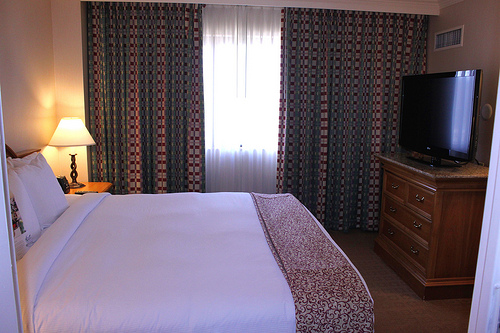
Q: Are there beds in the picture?
A: Yes, there is a bed.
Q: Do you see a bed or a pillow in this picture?
A: Yes, there is a bed.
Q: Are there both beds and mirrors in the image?
A: No, there is a bed but no mirrors.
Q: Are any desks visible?
A: No, there are no desks.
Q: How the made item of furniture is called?
A: The piece of furniture is a bed.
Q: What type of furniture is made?
A: The furniture is a bed.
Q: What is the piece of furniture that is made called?
A: The piece of furniture is a bed.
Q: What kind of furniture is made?
A: The furniture is a bed.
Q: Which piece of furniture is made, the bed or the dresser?
A: The bed is made.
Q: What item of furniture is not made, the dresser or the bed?
A: The dresser is not made.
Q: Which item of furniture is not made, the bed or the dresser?
A: The dresser is not made.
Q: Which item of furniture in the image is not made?
A: The piece of furniture is a dresser.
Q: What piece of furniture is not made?
A: The piece of furniture is a dresser.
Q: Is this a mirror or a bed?
A: This is a bed.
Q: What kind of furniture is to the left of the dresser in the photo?
A: The piece of furniture is a bed.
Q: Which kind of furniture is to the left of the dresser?
A: The piece of furniture is a bed.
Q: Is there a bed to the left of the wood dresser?
A: Yes, there is a bed to the left of the dresser.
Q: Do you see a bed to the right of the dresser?
A: No, the bed is to the left of the dresser.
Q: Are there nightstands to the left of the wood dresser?
A: No, there is a bed to the left of the dresser.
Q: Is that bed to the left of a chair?
A: No, the bed is to the left of a dresser.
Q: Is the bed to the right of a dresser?
A: No, the bed is to the left of a dresser.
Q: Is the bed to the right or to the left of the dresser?
A: The bed is to the left of the dresser.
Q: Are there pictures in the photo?
A: No, there are no pictures.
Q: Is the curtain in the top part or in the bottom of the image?
A: The curtain is in the top of the image.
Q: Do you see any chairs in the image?
A: No, there are no chairs.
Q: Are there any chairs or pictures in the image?
A: No, there are no chairs or pictures.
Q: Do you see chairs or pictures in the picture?
A: No, there are no chairs or pictures.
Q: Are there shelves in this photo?
A: No, there are no shelves.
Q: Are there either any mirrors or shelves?
A: No, there are no shelves or mirrors.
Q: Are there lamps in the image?
A: Yes, there is a lamp.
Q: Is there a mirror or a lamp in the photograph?
A: Yes, there is a lamp.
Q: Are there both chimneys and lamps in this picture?
A: No, there is a lamp but no chimneys.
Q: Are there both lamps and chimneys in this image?
A: No, there is a lamp but no chimneys.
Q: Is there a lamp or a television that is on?
A: Yes, the lamp is on.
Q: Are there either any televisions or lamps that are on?
A: Yes, the lamp is on.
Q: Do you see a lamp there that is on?
A: Yes, there is a lamp that is on.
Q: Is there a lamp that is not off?
A: Yes, there is a lamp that is on.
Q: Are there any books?
A: No, there are no books.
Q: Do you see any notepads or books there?
A: No, there are no books or notepads.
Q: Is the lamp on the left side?
A: Yes, the lamp is on the left of the image.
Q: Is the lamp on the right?
A: No, the lamp is on the left of the image.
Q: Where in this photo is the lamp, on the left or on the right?
A: The lamp is on the left of the image.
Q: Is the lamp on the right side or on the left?
A: The lamp is on the left of the image.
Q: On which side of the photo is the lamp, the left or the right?
A: The lamp is on the left of the image.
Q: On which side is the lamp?
A: The lamp is on the left of the image.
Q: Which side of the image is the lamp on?
A: The lamp is on the left of the image.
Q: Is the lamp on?
A: Yes, the lamp is on.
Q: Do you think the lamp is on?
A: Yes, the lamp is on.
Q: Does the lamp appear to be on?
A: Yes, the lamp is on.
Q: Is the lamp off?
A: No, the lamp is on.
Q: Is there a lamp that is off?
A: No, there is a lamp but it is on.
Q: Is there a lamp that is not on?
A: No, there is a lamp but it is on.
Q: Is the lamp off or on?
A: The lamp is on.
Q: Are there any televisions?
A: Yes, there is a television.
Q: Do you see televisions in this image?
A: Yes, there is a television.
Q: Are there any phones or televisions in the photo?
A: Yes, there is a television.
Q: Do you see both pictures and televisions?
A: No, there is a television but no pictures.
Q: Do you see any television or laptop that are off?
A: Yes, the television is off.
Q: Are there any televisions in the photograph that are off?
A: Yes, there is a television that is off.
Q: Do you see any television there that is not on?
A: Yes, there is a television that is off .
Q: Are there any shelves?
A: No, there are no shelves.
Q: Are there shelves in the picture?
A: No, there are no shelves.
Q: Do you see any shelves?
A: No, there are no shelves.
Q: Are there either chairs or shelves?
A: No, there are no shelves or chairs.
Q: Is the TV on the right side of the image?
A: Yes, the TV is on the right of the image.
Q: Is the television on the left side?
A: No, the television is on the right of the image.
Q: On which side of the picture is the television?
A: The television is on the right of the image.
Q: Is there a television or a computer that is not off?
A: No, there is a television but it is off.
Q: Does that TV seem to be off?
A: Yes, the TV is off.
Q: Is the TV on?
A: No, the TV is off.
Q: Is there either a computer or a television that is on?
A: No, there is a television but it is off.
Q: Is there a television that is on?
A: No, there is a television but it is off.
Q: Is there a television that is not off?
A: No, there is a television but it is off.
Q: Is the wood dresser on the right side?
A: Yes, the dresser is on the right of the image.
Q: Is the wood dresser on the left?
A: No, the dresser is on the right of the image.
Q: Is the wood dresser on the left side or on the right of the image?
A: The dresser is on the right of the image.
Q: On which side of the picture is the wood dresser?
A: The dresser is on the right of the image.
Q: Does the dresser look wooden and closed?
A: Yes, the dresser is wooden and closed.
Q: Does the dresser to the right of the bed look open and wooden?
A: No, the dresser is wooden but closed.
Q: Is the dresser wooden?
A: Yes, the dresser is wooden.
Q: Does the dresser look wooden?
A: Yes, the dresser is wooden.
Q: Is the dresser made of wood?
A: Yes, the dresser is made of wood.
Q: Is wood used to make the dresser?
A: Yes, the dresser is made of wood.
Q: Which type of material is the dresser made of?
A: The dresser is made of wood.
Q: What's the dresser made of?
A: The dresser is made of wood.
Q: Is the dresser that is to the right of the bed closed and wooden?
A: Yes, the dresser is closed and wooden.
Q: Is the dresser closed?
A: Yes, the dresser is closed.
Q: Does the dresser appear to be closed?
A: Yes, the dresser is closed.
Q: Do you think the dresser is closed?
A: Yes, the dresser is closed.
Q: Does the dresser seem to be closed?
A: Yes, the dresser is closed.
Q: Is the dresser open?
A: No, the dresser is closed.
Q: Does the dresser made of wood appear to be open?
A: No, the dresser is closed.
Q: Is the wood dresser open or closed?
A: The dresser is closed.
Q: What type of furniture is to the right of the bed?
A: The piece of furniture is a dresser.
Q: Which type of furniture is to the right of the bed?
A: The piece of furniture is a dresser.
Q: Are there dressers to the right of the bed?
A: Yes, there is a dresser to the right of the bed.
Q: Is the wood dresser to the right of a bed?
A: Yes, the dresser is to the right of a bed.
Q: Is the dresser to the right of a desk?
A: No, the dresser is to the right of a bed.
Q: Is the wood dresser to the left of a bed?
A: No, the dresser is to the right of a bed.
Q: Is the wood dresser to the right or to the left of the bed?
A: The dresser is to the right of the bed.